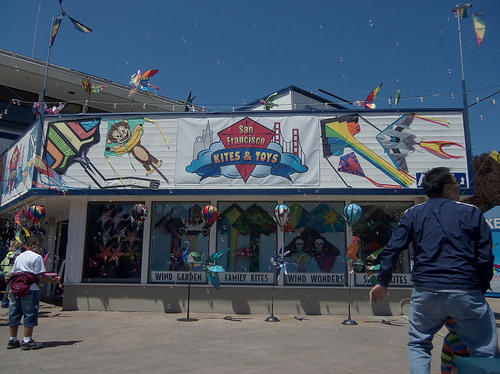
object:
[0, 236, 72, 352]
boy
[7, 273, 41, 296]
fanny pack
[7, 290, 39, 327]
jean shorts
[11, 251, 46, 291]
shirt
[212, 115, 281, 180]
san francisco kites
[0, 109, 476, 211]
sign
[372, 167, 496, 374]
man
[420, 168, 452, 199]
hair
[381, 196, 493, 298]
jacket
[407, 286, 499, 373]
jeans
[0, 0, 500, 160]
sky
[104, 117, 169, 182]
monkey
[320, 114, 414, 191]
kite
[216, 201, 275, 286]
sign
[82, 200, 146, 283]
window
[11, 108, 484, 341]
store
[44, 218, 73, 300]
door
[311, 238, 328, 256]
skull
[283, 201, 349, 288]
sign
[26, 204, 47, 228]
balls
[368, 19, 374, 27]
bubble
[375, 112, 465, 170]
kite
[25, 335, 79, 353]
shadow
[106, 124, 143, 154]
banana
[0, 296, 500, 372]
sidewalk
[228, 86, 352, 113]
building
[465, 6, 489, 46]
flag